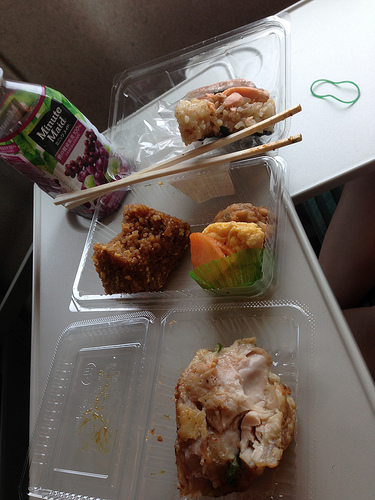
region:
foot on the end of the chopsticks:
[253, 135, 306, 156]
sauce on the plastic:
[67, 396, 120, 459]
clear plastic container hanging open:
[25, 297, 322, 499]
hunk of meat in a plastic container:
[32, 297, 335, 498]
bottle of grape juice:
[3, 79, 127, 227]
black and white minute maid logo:
[27, 95, 77, 151]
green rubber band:
[303, 63, 364, 116]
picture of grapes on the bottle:
[62, 133, 113, 190]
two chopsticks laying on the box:
[40, 104, 315, 303]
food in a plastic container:
[55, 13, 331, 307]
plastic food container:
[120, 319, 185, 499]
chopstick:
[123, 132, 157, 192]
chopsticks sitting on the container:
[210, 132, 312, 157]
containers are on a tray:
[50, 268, 106, 359]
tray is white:
[32, 234, 76, 292]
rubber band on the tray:
[307, 60, 365, 108]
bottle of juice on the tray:
[15, 65, 131, 244]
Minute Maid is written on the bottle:
[41, 105, 67, 136]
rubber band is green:
[317, 66, 373, 110]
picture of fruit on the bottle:
[74, 128, 110, 193]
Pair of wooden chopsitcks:
[59, 107, 304, 208]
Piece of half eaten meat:
[182, 351, 289, 485]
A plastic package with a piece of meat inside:
[18, 313, 318, 498]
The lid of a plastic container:
[15, 309, 160, 497]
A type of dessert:
[86, 206, 188, 290]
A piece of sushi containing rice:
[173, 77, 274, 144]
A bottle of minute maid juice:
[0, 67, 130, 217]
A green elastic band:
[307, 73, 360, 106]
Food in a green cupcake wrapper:
[190, 197, 271, 281]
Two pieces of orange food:
[189, 232, 229, 265]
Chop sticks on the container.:
[85, 157, 284, 186]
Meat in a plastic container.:
[106, 327, 293, 483]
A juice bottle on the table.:
[10, 84, 125, 221]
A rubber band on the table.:
[306, 67, 362, 140]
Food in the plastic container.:
[127, 214, 245, 284]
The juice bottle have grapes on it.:
[62, 139, 118, 185]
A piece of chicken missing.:
[206, 355, 263, 442]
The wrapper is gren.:
[184, 249, 268, 287]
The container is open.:
[58, 314, 345, 498]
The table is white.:
[276, 60, 359, 184]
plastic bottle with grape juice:
[12, 87, 122, 233]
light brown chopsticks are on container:
[63, 109, 314, 211]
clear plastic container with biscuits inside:
[97, 70, 289, 316]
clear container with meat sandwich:
[83, 311, 301, 480]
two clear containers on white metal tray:
[71, 69, 314, 492]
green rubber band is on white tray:
[308, 63, 348, 132]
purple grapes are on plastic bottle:
[48, 122, 115, 184]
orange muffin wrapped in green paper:
[182, 215, 259, 280]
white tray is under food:
[30, 178, 359, 484]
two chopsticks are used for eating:
[69, 107, 329, 204]